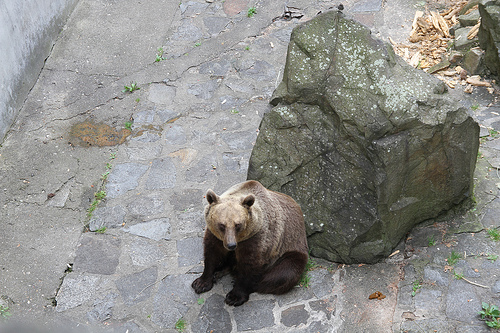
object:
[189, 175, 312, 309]
bear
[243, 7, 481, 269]
rock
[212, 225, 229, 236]
eye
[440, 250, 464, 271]
plants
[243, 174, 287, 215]
back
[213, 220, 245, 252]
muzzle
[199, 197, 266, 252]
head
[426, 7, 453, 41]
wood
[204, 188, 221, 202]
ears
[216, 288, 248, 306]
paws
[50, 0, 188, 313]
cracks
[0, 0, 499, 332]
platform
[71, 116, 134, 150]
poop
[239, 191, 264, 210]
ear